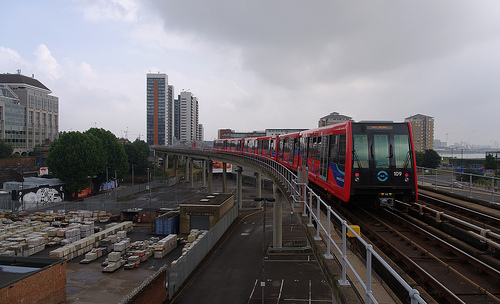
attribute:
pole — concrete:
[267, 187, 288, 251]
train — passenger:
[164, 116, 415, 203]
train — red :
[213, 119, 418, 211]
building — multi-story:
[136, 66, 177, 148]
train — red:
[207, 122, 422, 201]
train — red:
[178, 124, 423, 203]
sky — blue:
[3, 5, 498, 137]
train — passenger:
[211, 129, 427, 199]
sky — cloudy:
[0, 1, 499, 152]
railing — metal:
[260, 143, 371, 273]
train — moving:
[238, 114, 428, 201]